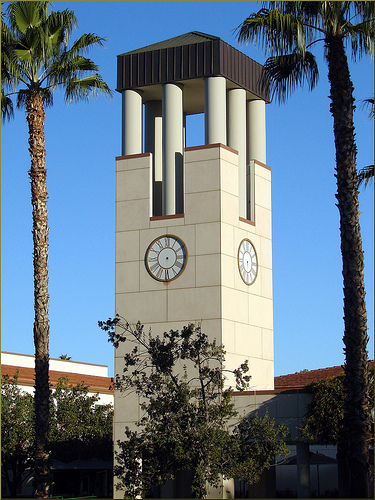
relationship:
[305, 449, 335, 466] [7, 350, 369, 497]
umbrella beside building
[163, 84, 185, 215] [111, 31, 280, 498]
column on clock tower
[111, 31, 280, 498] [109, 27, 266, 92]
clock tower has roof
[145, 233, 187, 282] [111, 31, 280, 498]
clock face in clock tower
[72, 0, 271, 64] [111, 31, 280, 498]
sky behind clock tower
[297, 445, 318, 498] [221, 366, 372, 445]
pillar on building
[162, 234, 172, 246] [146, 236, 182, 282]
roman numeral on clock face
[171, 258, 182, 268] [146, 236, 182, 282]
roman numeral on clock face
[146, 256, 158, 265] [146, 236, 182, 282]
roman numeral on clock face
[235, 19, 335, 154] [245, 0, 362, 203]
leaf on tree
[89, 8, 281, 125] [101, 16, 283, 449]
roof covering tower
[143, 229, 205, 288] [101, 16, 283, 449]
clock on side of tower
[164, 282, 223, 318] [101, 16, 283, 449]
brick on a tower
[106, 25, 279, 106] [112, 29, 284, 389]
pyramid on a tower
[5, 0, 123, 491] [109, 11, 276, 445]
tree near tower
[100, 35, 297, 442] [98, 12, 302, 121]
building with roof